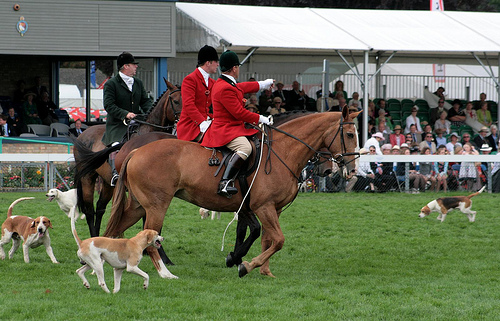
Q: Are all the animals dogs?
A: No, there are both horses and dogs.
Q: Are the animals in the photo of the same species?
A: No, they are horses and dogs.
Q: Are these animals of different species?
A: Yes, they are horses and dogs.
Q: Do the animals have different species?
A: Yes, they are horses and dogs.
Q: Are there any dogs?
A: Yes, there is a dog.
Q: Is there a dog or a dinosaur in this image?
A: Yes, there is a dog.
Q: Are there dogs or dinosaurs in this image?
A: Yes, there is a dog.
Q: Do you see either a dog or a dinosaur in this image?
A: Yes, there is a dog.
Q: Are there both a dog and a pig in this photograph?
A: No, there is a dog but no pigs.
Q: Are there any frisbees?
A: No, there are no frisbees.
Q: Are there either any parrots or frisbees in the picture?
A: No, there are no frisbees or parrots.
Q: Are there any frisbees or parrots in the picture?
A: No, there are no frisbees or parrots.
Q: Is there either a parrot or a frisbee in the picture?
A: No, there are no frisbees or parrots.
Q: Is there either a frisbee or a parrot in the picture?
A: No, there are no frisbees or parrots.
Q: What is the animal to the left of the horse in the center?
A: The animal is a dog.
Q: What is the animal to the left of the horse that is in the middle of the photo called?
A: The animal is a dog.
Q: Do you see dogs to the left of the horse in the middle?
A: Yes, there is a dog to the left of the horse.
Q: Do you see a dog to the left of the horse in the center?
A: Yes, there is a dog to the left of the horse.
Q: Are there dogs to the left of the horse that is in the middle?
A: Yes, there is a dog to the left of the horse.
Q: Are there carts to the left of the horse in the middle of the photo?
A: No, there is a dog to the left of the horse.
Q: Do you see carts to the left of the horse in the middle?
A: No, there is a dog to the left of the horse.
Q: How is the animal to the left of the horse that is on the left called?
A: The animal is a dog.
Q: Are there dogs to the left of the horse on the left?
A: Yes, there is a dog to the left of the horse.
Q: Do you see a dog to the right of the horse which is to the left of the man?
A: No, the dog is to the left of the horse.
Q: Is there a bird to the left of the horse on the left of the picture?
A: No, there is a dog to the left of the horse.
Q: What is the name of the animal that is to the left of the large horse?
A: The animal is a dog.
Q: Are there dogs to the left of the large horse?
A: Yes, there is a dog to the left of the horse.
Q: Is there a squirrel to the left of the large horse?
A: No, there is a dog to the left of the horse.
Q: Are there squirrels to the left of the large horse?
A: No, there is a dog to the left of the horse.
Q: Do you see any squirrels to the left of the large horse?
A: No, there is a dog to the left of the horse.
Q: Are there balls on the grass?
A: No, there is a dog on the grass.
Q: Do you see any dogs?
A: Yes, there is a dog.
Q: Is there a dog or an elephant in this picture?
A: Yes, there is a dog.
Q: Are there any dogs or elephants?
A: Yes, there is a dog.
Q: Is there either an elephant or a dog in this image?
A: Yes, there is a dog.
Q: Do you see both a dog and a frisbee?
A: No, there is a dog but no frisbees.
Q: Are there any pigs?
A: No, there are no pigs.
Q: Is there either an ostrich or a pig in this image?
A: No, there are no pigs or ostriches.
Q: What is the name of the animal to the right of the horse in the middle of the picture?
A: The animal is a dog.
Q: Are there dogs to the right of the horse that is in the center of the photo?
A: Yes, there is a dog to the right of the horse.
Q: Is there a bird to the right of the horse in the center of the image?
A: No, there is a dog to the right of the horse.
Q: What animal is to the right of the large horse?
A: The animal is a dog.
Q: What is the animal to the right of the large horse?
A: The animal is a dog.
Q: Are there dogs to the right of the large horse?
A: Yes, there is a dog to the right of the horse.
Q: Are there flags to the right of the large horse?
A: No, there is a dog to the right of the horse.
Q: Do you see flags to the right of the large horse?
A: No, there is a dog to the right of the horse.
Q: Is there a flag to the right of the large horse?
A: No, there is a dog to the right of the horse.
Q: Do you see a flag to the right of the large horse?
A: No, there is a dog to the right of the horse.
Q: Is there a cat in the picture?
A: No, there are no cats.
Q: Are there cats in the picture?
A: No, there are no cats.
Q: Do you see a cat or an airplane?
A: No, there are no cats or airplanes.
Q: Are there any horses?
A: Yes, there is a horse.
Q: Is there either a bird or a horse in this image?
A: Yes, there is a horse.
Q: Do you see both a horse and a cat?
A: No, there is a horse but no cats.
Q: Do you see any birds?
A: No, there are no birds.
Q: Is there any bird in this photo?
A: No, there are no birds.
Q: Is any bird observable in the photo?
A: No, there are no birds.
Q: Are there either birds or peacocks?
A: No, there are no birds or peacocks.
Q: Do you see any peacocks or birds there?
A: No, there are no birds or peacocks.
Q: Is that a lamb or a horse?
A: That is a horse.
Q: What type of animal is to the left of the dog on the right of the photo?
A: The animal is a horse.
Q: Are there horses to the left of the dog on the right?
A: Yes, there is a horse to the left of the dog.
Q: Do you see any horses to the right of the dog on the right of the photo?
A: No, the horse is to the left of the dog.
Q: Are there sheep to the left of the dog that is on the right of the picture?
A: No, there is a horse to the left of the dog.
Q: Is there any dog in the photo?
A: Yes, there is a dog.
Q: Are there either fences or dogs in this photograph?
A: Yes, there is a dog.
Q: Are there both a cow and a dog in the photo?
A: No, there is a dog but no cows.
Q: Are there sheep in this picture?
A: No, there are no sheep.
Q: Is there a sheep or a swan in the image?
A: No, there are no sheep or swans.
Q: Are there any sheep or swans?
A: No, there are no sheep or swans.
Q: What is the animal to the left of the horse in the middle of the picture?
A: The animal is a dog.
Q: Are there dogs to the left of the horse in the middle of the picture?
A: Yes, there is a dog to the left of the horse.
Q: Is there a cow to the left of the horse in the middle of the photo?
A: No, there is a dog to the left of the horse.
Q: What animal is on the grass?
A: The animal is a dog.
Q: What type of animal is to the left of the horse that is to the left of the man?
A: The animal is a dog.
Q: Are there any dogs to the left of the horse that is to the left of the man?
A: Yes, there is a dog to the left of the horse.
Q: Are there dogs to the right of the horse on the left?
A: No, the dog is to the left of the horse.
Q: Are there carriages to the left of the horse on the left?
A: No, there is a dog to the left of the horse.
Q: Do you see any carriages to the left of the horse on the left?
A: No, there is a dog to the left of the horse.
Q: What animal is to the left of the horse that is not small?
A: The animal is a dog.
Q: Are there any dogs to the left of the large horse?
A: Yes, there is a dog to the left of the horse.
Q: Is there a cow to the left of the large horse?
A: No, there is a dog to the left of the horse.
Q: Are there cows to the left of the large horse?
A: No, there is a dog to the left of the horse.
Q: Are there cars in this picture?
A: No, there are no cars.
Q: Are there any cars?
A: No, there are no cars.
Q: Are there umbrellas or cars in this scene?
A: No, there are no cars or umbrellas.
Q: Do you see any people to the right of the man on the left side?
A: Yes, there are people to the right of the man.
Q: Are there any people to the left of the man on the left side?
A: No, the people are to the right of the man.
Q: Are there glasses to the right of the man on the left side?
A: No, there are people to the right of the man.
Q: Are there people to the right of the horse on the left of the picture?
A: Yes, there are people to the right of the horse.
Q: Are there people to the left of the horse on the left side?
A: No, the people are to the right of the horse.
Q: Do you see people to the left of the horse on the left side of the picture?
A: No, the people are to the right of the horse.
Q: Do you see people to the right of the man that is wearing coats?
A: Yes, there are people to the right of the man.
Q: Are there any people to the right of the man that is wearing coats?
A: Yes, there are people to the right of the man.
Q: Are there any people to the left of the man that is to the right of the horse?
A: No, the people are to the right of the man.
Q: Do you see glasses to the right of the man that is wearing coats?
A: No, there are people to the right of the man.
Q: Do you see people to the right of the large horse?
A: Yes, there are people to the right of the horse.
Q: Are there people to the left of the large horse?
A: No, the people are to the right of the horse.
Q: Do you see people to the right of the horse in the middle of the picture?
A: Yes, there are people to the right of the horse.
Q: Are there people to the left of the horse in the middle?
A: No, the people are to the right of the horse.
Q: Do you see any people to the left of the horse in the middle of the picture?
A: No, the people are to the right of the horse.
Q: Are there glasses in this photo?
A: No, there are no glasses.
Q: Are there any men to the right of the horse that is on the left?
A: Yes, there is a man to the right of the horse.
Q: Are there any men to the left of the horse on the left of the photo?
A: No, the man is to the right of the horse.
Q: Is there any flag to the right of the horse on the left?
A: No, there is a man to the right of the horse.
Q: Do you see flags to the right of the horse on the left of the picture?
A: No, there is a man to the right of the horse.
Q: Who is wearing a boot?
A: The man is wearing a boot.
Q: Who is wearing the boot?
A: The man is wearing a boot.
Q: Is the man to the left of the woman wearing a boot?
A: Yes, the man is wearing a boot.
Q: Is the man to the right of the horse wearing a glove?
A: No, the man is wearing a boot.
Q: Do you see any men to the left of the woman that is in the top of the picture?
A: Yes, there is a man to the left of the woman.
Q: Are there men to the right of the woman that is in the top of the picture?
A: No, the man is to the left of the woman.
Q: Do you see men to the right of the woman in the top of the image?
A: No, the man is to the left of the woman.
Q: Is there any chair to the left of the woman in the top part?
A: No, there is a man to the left of the woman.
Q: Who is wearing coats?
A: The man is wearing coats.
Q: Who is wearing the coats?
A: The man is wearing coats.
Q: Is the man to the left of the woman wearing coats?
A: Yes, the man is wearing coats.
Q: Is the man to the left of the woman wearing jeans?
A: No, the man is wearing coats.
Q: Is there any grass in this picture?
A: Yes, there is grass.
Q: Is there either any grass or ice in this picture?
A: Yes, there is grass.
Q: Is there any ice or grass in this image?
A: Yes, there is grass.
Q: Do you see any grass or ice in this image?
A: Yes, there is grass.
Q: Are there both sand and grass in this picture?
A: No, there is grass but no sand.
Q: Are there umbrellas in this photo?
A: No, there are no umbrellas.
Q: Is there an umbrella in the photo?
A: No, there are no umbrellas.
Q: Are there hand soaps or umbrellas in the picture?
A: No, there are no umbrellas or hand soaps.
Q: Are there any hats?
A: Yes, there is a hat.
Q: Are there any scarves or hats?
A: Yes, there is a hat.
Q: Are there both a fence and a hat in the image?
A: Yes, there are both a hat and a fence.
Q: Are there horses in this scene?
A: Yes, there is a horse.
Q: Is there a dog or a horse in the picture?
A: Yes, there is a horse.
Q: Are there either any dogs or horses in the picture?
A: Yes, there is a horse.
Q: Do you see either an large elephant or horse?
A: Yes, there is a large horse.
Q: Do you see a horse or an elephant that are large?
A: Yes, the horse is large.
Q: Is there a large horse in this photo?
A: Yes, there is a large horse.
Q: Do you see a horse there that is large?
A: Yes, there is a horse that is large.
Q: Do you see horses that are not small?
A: Yes, there is a large horse.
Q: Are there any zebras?
A: No, there are no zebras.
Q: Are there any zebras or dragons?
A: No, there are no zebras or dragons.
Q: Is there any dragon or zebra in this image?
A: No, there are no zebras or dragons.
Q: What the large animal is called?
A: The animal is a horse.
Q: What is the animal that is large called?
A: The animal is a horse.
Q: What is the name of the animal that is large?
A: The animal is a horse.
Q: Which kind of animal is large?
A: The animal is a horse.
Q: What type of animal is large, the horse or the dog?
A: The horse is large.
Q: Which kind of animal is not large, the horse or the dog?
A: The dog is not large.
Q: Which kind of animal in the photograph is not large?
A: The animal is a dog.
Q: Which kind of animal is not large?
A: The animal is a dog.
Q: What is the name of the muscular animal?
A: The animal is a horse.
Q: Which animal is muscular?
A: The animal is a horse.